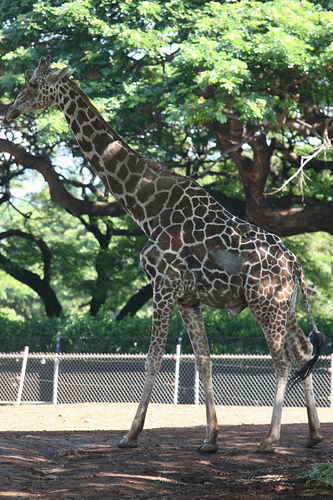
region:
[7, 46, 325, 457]
Animal pictured is a giraffe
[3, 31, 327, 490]
Giraffe is standing in place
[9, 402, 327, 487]
Ground is made of dirt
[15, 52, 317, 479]
You can only see the left of the giraffe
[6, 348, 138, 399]
Wire fence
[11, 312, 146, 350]
Green bushes behind the fence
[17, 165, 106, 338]
Large trees behind green bushes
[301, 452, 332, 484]
Patch of green on the ground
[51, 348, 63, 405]
Fence posts made of metal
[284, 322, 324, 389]
Black furry tail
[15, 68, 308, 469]
a giraffe is all alone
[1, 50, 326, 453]
one giraffe standing in shade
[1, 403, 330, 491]
shadow on ground creating shade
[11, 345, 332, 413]
a chain link fence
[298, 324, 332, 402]
long black hairs on tail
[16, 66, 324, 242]
large tree branch next to giraffe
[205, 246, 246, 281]
a gray spot on the giraffe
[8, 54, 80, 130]
head of a giraffe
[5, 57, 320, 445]
a brown and white giraffe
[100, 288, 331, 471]
four long legs of giraffe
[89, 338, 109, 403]
There is a metal fence that is in the background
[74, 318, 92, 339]
There are green trees in the background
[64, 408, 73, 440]
There is brown gravel on the ground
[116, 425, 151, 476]
The giraffes have large hooves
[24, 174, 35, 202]
There is a light blue that is visible in the sky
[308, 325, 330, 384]
The giraffe has a black tail that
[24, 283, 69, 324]
There is a brown trunk that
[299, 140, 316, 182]
There is a small branch that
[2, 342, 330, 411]
Metal chain link fence of enclosure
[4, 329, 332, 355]
Barbed wire at top of fence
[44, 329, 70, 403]
Metal pole of enclosure fence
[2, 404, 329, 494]
Enclosure ground covered with dirt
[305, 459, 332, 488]
Patch of green grass in enclosure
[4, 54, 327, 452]
Giraffe walking in enclosure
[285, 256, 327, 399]
Swishing tail of giraffe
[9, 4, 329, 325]
Summer trees behind enclosure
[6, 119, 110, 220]
Patches of sunshine through the trees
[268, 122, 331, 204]
Dead branch on tree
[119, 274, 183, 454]
Giraffe front left left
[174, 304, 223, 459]
Giraffe front right leg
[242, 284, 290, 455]
giraffe back left leg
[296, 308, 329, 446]
giraffe back right leg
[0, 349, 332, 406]
A small enclosure fence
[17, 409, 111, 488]
Dirt on the ground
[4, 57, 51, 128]
The face of giraffe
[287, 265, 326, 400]
A giraffes hind tale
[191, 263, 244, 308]
A giraffes hanging belly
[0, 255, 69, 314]
The trunk of a tree